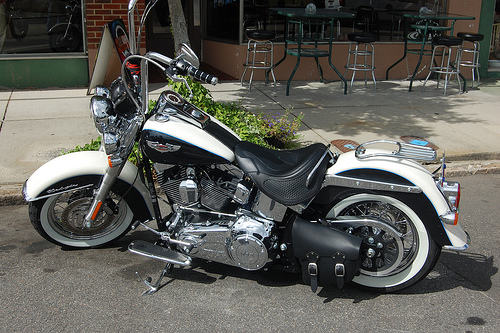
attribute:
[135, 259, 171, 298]
kick stand — metal, chrome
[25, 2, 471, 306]
motorcycle — parked, black, white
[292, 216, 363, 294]
bad — black, double buckled, a saddle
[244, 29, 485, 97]
chairs — metal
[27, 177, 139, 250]
tire — black, white, wide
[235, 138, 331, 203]
cushion — black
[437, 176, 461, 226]
tail light — chrome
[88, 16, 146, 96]
sandwich board — seen from the side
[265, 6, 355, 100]
table — green, outdoors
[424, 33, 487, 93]
stools — black, grey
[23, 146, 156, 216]
fender — white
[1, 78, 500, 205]
sidewalk — concrete